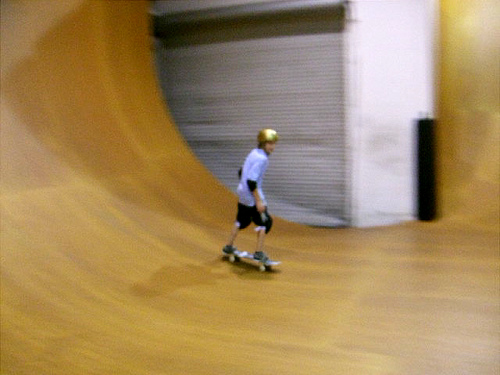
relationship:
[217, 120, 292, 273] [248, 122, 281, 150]
boy wearing helmet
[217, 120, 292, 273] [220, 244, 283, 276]
boy riding skateboard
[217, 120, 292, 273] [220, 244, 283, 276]
guy on skateboard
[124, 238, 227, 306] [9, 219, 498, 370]
shadow on ground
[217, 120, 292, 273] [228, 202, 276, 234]
boy wearing black pants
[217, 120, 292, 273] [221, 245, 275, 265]
boy has black shoes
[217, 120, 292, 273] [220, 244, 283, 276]
man riding on skateboard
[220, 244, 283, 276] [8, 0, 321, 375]
skateboard on ramp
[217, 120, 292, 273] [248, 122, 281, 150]
man has helmet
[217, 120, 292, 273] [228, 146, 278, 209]
man wearing blue shirt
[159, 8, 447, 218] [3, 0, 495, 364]
wall near wooden ramp